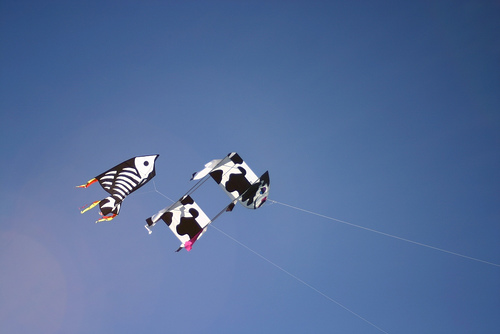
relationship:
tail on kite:
[176, 234, 202, 264] [147, 194, 217, 264]